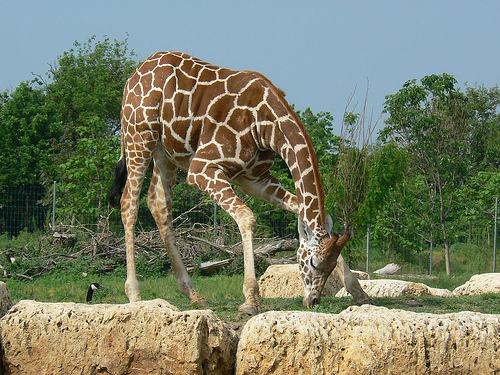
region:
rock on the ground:
[253, 243, 496, 313]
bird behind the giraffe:
[81, 275, 108, 306]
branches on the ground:
[21, 216, 278, 277]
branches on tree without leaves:
[333, 80, 376, 257]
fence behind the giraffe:
[6, 178, 143, 228]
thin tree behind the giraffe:
[386, 75, 459, 217]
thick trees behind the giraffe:
[7, 57, 126, 201]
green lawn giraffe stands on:
[26, 270, 468, 322]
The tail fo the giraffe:
[111, 131, 125, 205]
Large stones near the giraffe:
[2, 300, 499, 372]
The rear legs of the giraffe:
[123, 137, 205, 304]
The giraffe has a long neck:
[269, 103, 324, 228]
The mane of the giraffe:
[272, 92, 324, 228]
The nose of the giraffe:
[309, 293, 321, 310]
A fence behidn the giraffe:
[4, 179, 499, 272]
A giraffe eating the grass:
[109, 52, 368, 304]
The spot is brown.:
[157, 51, 184, 69]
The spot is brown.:
[169, 116, 192, 140]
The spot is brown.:
[133, 102, 146, 125]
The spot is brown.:
[253, 102, 277, 124]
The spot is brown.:
[293, 142, 313, 174]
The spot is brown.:
[301, 167, 319, 197]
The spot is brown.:
[188, 155, 209, 176]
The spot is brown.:
[303, 191, 314, 208]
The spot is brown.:
[285, 145, 298, 170]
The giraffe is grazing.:
[268, 103, 370, 319]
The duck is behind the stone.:
[61, 270, 111, 307]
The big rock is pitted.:
[6, 295, 230, 372]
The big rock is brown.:
[3, 292, 211, 374]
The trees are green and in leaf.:
[386, 63, 479, 269]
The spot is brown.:
[153, 62, 170, 92]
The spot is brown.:
[176, 68, 201, 98]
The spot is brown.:
[190, 76, 217, 120]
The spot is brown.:
[229, 104, 255, 138]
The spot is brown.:
[191, 158, 205, 173]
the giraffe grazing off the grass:
[290, 215, 348, 308]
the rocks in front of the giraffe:
[8, 302, 498, 374]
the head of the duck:
[83, 277, 107, 306]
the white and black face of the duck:
[88, 279, 105, 294]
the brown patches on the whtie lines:
[118, 48, 370, 316]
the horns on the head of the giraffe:
[325, 225, 353, 253]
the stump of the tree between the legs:
[255, 230, 295, 262]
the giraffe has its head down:
[72, 41, 391, 333]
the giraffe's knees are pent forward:
[185, 143, 383, 305]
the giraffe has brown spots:
[92, 23, 395, 333]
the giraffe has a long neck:
[94, 28, 381, 323]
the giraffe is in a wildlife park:
[25, 35, 452, 373]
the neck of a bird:
[79, 266, 125, 322]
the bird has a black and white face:
[67, 262, 122, 329]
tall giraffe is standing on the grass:
[105, 41, 392, 313]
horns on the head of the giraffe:
[326, 225, 349, 246]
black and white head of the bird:
[80, 275, 106, 305]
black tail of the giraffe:
[102, 153, 126, 209]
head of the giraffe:
[286, 210, 359, 313]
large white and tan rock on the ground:
[236, 315, 490, 372]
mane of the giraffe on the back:
[289, 114, 316, 161]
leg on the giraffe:
[208, 172, 265, 322]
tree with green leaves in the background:
[311, 121, 338, 159]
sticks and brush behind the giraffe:
[67, 238, 123, 266]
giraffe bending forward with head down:
[108, 43, 381, 318]